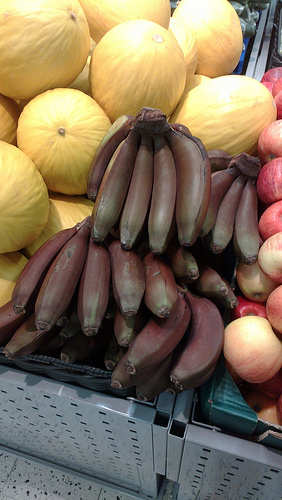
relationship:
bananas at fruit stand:
[0, 105, 265, 406] [0, 0, 280, 499]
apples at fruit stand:
[223, 65, 281, 422] [0, 0, 280, 499]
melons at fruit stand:
[0, 1, 276, 304] [0, 0, 280, 499]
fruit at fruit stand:
[0, 1, 281, 434] [0, 0, 280, 499]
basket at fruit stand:
[0, 347, 178, 497] [0, 0, 280, 499]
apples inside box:
[223, 65, 281, 422] [203, 355, 280, 447]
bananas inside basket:
[0, 105, 265, 406] [1, 337, 140, 397]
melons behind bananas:
[0, 1, 276, 304] [0, 105, 265, 406]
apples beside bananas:
[223, 65, 281, 422] [0, 105, 265, 406]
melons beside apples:
[0, 1, 276, 304] [223, 65, 281, 422]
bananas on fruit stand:
[0, 105, 265, 406] [0, 0, 280, 499]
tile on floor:
[0, 449, 151, 499] [2, 444, 153, 498]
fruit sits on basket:
[0, 1, 281, 434] [0, 347, 178, 497]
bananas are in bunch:
[0, 105, 265, 406] [88, 104, 214, 258]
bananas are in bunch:
[0, 105, 265, 406] [196, 145, 267, 267]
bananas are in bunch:
[0, 105, 265, 406] [10, 212, 178, 338]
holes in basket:
[126, 409, 146, 473] [0, 347, 178, 497]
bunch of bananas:
[88, 104, 214, 258] [0, 105, 265, 406]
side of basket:
[2, 366, 281, 499] [0, 347, 178, 497]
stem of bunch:
[134, 100, 170, 136] [88, 104, 214, 258]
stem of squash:
[55, 121, 69, 138] [13, 83, 116, 198]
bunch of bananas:
[10, 212, 178, 338] [0, 105, 265, 406]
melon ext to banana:
[17, 89, 111, 195] [88, 108, 129, 209]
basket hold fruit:
[0, 347, 178, 497] [0, 1, 281, 434]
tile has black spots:
[0, 449, 151, 499] [20, 472, 66, 498]